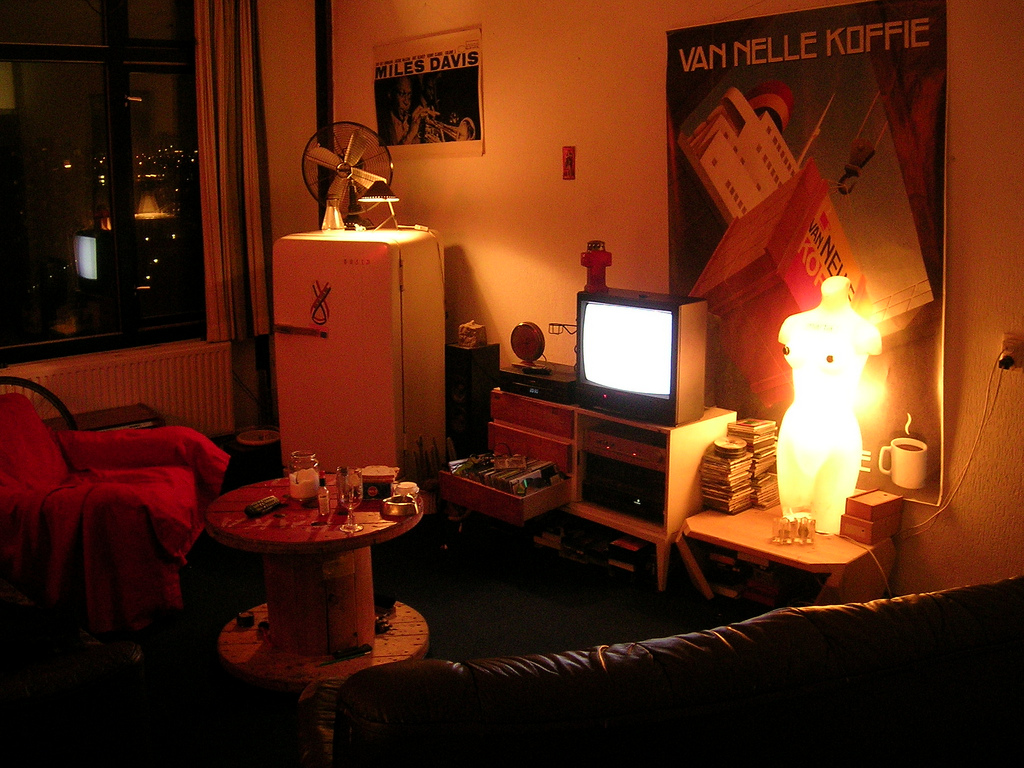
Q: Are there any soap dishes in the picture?
A: No, there are no soap dishes.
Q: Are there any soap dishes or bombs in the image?
A: No, there are no soap dishes or bombs.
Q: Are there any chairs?
A: Yes, there is a chair.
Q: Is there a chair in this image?
A: Yes, there is a chair.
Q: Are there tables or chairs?
A: Yes, there is a chair.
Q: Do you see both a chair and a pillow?
A: No, there is a chair but no pillows.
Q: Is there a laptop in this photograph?
A: No, there are no laptops.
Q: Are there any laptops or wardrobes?
A: No, there are no laptops or wardrobes.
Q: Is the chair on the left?
A: Yes, the chair is on the left of the image.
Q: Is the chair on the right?
A: No, the chair is on the left of the image.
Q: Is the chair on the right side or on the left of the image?
A: The chair is on the left of the image.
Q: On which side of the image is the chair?
A: The chair is on the left of the image.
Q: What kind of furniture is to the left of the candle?
A: The piece of furniture is a chair.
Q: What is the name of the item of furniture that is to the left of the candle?
A: The piece of furniture is a chair.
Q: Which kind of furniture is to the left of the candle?
A: The piece of furniture is a chair.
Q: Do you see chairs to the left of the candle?
A: Yes, there is a chair to the left of the candle.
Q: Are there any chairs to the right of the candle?
A: No, the chair is to the left of the candle.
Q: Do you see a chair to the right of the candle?
A: No, the chair is to the left of the candle.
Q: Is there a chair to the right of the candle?
A: No, the chair is to the left of the candle.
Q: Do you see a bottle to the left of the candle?
A: No, there is a chair to the left of the candle.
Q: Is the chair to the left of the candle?
A: Yes, the chair is to the left of the candle.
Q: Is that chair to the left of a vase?
A: No, the chair is to the left of the candle.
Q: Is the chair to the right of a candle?
A: No, the chair is to the left of a candle.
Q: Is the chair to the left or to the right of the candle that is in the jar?
A: The chair is to the left of the candle.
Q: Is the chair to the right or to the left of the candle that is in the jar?
A: The chair is to the left of the candle.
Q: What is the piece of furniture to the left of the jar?
A: The piece of furniture is a chair.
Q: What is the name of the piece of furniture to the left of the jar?
A: The piece of furniture is a chair.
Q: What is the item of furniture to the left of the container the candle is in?
A: The piece of furniture is a chair.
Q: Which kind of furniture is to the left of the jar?
A: The piece of furniture is a chair.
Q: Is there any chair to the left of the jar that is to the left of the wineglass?
A: Yes, there is a chair to the left of the jar.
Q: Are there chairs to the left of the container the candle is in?
A: Yes, there is a chair to the left of the jar.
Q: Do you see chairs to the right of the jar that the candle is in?
A: No, the chair is to the left of the jar.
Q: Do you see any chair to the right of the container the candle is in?
A: No, the chair is to the left of the jar.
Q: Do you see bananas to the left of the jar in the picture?
A: No, there is a chair to the left of the jar.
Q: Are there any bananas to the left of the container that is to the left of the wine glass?
A: No, there is a chair to the left of the jar.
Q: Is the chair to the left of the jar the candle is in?
A: Yes, the chair is to the left of the jar.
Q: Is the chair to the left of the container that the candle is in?
A: Yes, the chair is to the left of the jar.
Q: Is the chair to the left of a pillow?
A: No, the chair is to the left of the jar.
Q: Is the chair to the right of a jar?
A: No, the chair is to the left of a jar.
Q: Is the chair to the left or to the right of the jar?
A: The chair is to the left of the jar.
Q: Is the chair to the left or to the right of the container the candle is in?
A: The chair is to the left of the jar.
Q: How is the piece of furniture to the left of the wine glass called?
A: The piece of furniture is a chair.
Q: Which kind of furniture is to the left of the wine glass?
A: The piece of furniture is a chair.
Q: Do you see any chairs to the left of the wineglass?
A: Yes, there is a chair to the left of the wineglass.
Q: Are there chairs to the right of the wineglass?
A: No, the chair is to the left of the wineglass.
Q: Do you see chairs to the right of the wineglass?
A: No, the chair is to the left of the wineglass.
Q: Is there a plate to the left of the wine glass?
A: No, there is a chair to the left of the wine glass.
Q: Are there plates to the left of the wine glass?
A: No, there is a chair to the left of the wine glass.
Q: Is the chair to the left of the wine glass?
A: Yes, the chair is to the left of the wine glass.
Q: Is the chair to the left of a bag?
A: No, the chair is to the left of the wine glass.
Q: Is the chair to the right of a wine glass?
A: No, the chair is to the left of a wine glass.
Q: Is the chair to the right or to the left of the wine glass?
A: The chair is to the left of the wine glass.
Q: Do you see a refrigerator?
A: Yes, there is a refrigerator.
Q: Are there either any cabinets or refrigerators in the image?
A: Yes, there is a refrigerator.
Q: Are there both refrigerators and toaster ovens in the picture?
A: No, there is a refrigerator but no toaster ovens.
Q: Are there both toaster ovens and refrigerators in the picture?
A: No, there is a refrigerator but no toaster ovens.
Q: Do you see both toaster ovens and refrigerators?
A: No, there is a refrigerator but no toaster ovens.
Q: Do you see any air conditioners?
A: No, there are no air conditioners.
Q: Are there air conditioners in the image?
A: No, there are no air conditioners.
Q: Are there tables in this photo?
A: Yes, there is a table.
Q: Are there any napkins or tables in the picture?
A: Yes, there is a table.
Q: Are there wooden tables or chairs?
A: Yes, there is a wood table.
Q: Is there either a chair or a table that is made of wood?
A: Yes, the table is made of wood.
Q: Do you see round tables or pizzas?
A: Yes, there is a round table.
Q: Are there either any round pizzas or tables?
A: Yes, there is a round table.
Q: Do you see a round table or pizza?
A: Yes, there is a round table.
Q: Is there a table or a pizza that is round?
A: Yes, the table is round.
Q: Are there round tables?
A: Yes, there is a round table.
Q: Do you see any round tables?
A: Yes, there is a round table.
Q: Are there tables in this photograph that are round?
A: Yes, there is a round table.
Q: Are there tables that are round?
A: Yes, there is a table that is round.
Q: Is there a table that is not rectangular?
A: Yes, there is a round table.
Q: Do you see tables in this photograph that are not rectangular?
A: Yes, there is a round table.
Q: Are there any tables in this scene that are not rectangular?
A: Yes, there is a round table.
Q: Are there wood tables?
A: Yes, there is a table that is made of wood.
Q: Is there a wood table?
A: Yes, there is a table that is made of wood.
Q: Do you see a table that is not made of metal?
A: Yes, there is a table that is made of wood.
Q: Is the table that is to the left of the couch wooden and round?
A: Yes, the table is wooden and round.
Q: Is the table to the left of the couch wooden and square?
A: No, the table is wooden but round.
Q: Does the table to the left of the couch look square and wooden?
A: No, the table is wooden but round.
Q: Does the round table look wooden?
A: Yes, the table is wooden.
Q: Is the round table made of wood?
A: Yes, the table is made of wood.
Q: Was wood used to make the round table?
A: Yes, the table is made of wood.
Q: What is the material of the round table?
A: The table is made of wood.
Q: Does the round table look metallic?
A: No, the table is wooden.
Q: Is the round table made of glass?
A: No, the table is made of wood.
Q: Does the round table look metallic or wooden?
A: The table is wooden.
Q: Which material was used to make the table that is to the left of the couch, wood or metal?
A: The table is made of wood.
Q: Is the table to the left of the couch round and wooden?
A: Yes, the table is round and wooden.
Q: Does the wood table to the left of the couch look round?
A: Yes, the table is round.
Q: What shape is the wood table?
A: The table is round.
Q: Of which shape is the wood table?
A: The table is round.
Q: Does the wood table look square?
A: No, the table is round.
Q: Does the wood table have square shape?
A: No, the table is round.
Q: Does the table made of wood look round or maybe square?
A: The table is round.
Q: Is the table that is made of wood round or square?
A: The table is round.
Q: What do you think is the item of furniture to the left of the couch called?
A: The piece of furniture is a table.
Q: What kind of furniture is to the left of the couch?
A: The piece of furniture is a table.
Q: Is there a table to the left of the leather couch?
A: Yes, there is a table to the left of the couch.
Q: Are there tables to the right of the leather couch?
A: No, the table is to the left of the couch.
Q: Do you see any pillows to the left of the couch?
A: No, there is a table to the left of the couch.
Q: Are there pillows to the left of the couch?
A: No, there is a table to the left of the couch.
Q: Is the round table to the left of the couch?
A: Yes, the table is to the left of the couch.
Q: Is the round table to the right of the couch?
A: No, the table is to the left of the couch.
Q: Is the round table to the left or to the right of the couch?
A: The table is to the left of the couch.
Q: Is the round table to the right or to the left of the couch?
A: The table is to the left of the couch.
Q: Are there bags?
A: No, there are no bags.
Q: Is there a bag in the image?
A: No, there are no bags.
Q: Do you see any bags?
A: No, there are no bags.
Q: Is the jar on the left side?
A: Yes, the jar is on the left of the image.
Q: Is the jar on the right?
A: No, the jar is on the left of the image.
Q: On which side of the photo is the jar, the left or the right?
A: The jar is on the left of the image.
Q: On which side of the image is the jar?
A: The jar is on the left of the image.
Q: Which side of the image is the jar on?
A: The jar is on the left of the image.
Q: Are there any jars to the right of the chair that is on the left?
A: Yes, there is a jar to the right of the chair.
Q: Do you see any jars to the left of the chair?
A: No, the jar is to the right of the chair.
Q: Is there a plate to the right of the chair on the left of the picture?
A: No, there is a jar to the right of the chair.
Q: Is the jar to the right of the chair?
A: Yes, the jar is to the right of the chair.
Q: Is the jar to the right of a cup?
A: No, the jar is to the right of the chair.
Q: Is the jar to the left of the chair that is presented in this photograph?
A: No, the jar is to the right of the chair.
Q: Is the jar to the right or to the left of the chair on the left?
A: The jar is to the right of the chair.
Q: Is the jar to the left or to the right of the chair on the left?
A: The jar is to the right of the chair.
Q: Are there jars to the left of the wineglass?
A: Yes, there is a jar to the left of the wineglass.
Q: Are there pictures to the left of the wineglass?
A: No, there is a jar to the left of the wineglass.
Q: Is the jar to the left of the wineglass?
A: Yes, the jar is to the left of the wineglass.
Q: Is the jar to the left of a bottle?
A: No, the jar is to the left of the wineglass.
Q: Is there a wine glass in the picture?
A: Yes, there is a wine glass.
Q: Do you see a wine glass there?
A: Yes, there is a wine glass.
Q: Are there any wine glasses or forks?
A: Yes, there is a wine glass.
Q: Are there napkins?
A: No, there are no napkins.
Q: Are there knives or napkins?
A: No, there are no napkins or knives.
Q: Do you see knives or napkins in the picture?
A: No, there are no napkins or knives.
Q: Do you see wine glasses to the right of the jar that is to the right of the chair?
A: Yes, there is a wine glass to the right of the jar.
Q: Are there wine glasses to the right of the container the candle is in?
A: Yes, there is a wine glass to the right of the jar.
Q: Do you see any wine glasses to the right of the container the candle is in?
A: Yes, there is a wine glass to the right of the jar.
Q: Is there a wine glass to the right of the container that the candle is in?
A: Yes, there is a wine glass to the right of the jar.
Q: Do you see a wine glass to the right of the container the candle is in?
A: Yes, there is a wine glass to the right of the jar.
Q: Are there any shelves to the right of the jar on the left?
A: No, there is a wine glass to the right of the jar.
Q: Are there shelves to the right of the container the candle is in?
A: No, there is a wine glass to the right of the jar.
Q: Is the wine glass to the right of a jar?
A: Yes, the wine glass is to the right of a jar.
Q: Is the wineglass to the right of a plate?
A: No, the wineglass is to the right of a jar.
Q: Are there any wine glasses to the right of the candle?
A: Yes, there is a wine glass to the right of the candle.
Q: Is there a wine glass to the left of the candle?
A: No, the wine glass is to the right of the candle.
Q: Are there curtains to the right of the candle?
A: No, there is a wine glass to the right of the candle.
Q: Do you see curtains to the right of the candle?
A: No, there is a wine glass to the right of the candle.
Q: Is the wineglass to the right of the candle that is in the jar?
A: Yes, the wineglass is to the right of the candle.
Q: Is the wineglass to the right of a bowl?
A: No, the wineglass is to the right of the candle.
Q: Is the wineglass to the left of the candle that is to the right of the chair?
A: No, the wineglass is to the right of the candle.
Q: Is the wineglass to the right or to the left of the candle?
A: The wineglass is to the right of the candle.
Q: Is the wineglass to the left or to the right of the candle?
A: The wineglass is to the right of the candle.